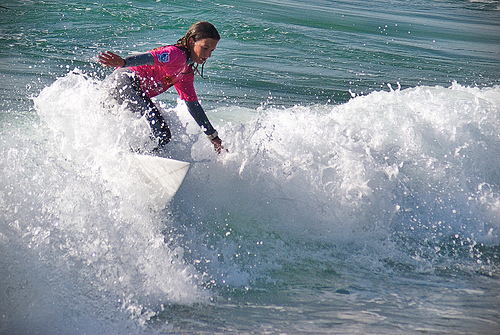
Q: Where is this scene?
A: Ocean.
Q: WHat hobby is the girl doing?
A: Surfing.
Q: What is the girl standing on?
A: Surfboard.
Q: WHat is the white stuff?
A: Foam.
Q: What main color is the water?
A: Sea green.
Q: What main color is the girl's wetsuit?
A: Pink.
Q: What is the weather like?
A: Fair.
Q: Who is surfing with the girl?
A: No person.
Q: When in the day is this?
A: Afternoon.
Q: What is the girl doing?
A: Surfboarding.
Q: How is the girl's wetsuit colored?
A: Pink.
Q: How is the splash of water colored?
A: White.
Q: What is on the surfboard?
A: The woman.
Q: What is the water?
A: Raised.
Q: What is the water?
A: Bluish green.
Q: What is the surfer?
A: The girl.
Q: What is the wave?
A: Rising.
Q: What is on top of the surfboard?
A: Girl wearing pink.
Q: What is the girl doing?
A: Surfing.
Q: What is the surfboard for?
A: Surfing.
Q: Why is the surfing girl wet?
A: Water from the ocean.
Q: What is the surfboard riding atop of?
A: Wave.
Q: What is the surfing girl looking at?
A: Water.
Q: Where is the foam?
A: On the wave.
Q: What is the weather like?
A: Sunny.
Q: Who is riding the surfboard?
A: Girl wearing pink.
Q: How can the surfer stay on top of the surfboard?
A: Balance.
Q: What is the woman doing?
A: Surfing.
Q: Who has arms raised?
A: The surfer.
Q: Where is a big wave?
A: In the ocean.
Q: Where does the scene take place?
A: In the ocean.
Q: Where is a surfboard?
A: Under woman's feet.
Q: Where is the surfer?
A: In the ocean.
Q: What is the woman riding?
A: A wave.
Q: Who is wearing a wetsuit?
A: The surfer.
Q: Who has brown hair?
A: The woman.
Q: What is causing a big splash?
A: A big wave.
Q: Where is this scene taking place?
A: In the ocean.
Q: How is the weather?
A: Hot and sunny.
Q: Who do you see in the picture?
A: A teenage girl.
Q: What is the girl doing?
A: Surfing.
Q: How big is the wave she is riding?
A: Not very big at all.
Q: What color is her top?
A: Pink.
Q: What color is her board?
A: White.